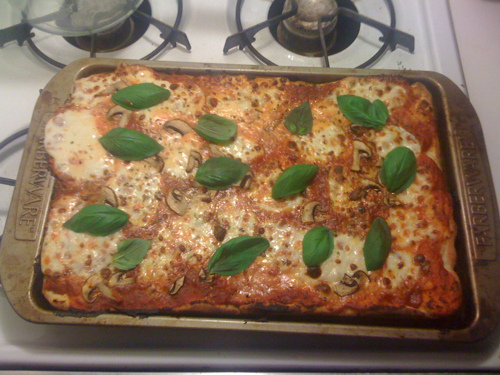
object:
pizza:
[40, 65, 462, 320]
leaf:
[98, 127, 164, 161]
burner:
[275, 1, 343, 56]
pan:
[0, 57, 499, 343]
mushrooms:
[165, 187, 188, 217]